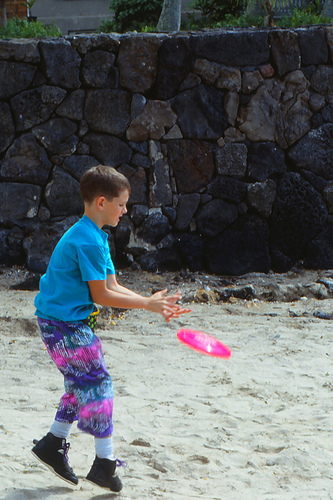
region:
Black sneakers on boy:
[28, 431, 126, 491]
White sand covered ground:
[5, 269, 331, 497]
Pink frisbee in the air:
[172, 326, 233, 358]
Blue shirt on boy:
[34, 216, 122, 322]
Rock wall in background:
[0, 24, 331, 272]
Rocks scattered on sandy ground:
[4, 270, 329, 322]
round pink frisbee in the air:
[163, 323, 235, 363]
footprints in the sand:
[172, 436, 246, 473]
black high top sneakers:
[83, 454, 131, 496]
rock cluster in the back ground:
[164, 141, 325, 219]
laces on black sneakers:
[57, 437, 76, 452]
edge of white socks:
[79, 430, 127, 460]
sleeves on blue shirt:
[58, 229, 124, 292]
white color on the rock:
[16, 199, 43, 225]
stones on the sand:
[196, 263, 307, 314]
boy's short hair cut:
[69, 164, 145, 206]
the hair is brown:
[80, 163, 128, 205]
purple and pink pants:
[36, 317, 113, 435]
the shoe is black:
[31, 432, 79, 484]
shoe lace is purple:
[116, 458, 122, 465]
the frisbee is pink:
[178, 327, 228, 357]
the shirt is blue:
[34, 214, 114, 321]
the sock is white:
[93, 437, 113, 461]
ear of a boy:
[97, 196, 104, 208]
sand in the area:
[0, 290, 331, 498]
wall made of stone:
[0, 32, 332, 267]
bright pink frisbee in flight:
[173, 322, 231, 359]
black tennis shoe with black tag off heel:
[25, 428, 76, 484]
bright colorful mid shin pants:
[32, 308, 113, 434]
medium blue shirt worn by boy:
[32, 209, 110, 320]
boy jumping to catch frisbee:
[27, 160, 190, 493]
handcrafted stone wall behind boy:
[1, 21, 328, 274]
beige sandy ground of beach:
[0, 286, 330, 494]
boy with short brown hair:
[76, 161, 125, 202]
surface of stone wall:
[2, 28, 330, 276]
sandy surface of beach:
[2, 290, 331, 498]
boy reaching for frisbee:
[32, 164, 232, 493]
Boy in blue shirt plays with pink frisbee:
[31, 162, 192, 494]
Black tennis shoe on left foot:
[29, 430, 79, 487]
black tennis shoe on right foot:
[85, 454, 124, 492]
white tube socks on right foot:
[94, 435, 115, 462]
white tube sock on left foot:
[46, 419, 71, 438]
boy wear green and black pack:
[84, 302, 99, 330]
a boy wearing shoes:
[13, 429, 128, 497]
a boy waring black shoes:
[41, 432, 150, 498]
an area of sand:
[142, 371, 280, 486]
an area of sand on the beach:
[180, 365, 327, 470]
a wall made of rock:
[161, 165, 331, 307]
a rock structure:
[167, 109, 315, 330]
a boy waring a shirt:
[43, 159, 139, 384]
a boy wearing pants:
[39, 297, 107, 444]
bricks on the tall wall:
[120, 66, 245, 144]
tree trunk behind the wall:
[151, 3, 200, 30]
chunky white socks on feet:
[84, 429, 137, 458]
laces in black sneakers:
[57, 436, 73, 454]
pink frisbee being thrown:
[167, 319, 242, 355]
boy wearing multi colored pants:
[34, 303, 126, 441]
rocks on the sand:
[216, 273, 291, 306]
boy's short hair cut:
[74, 159, 137, 209]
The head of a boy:
[76, 160, 134, 233]